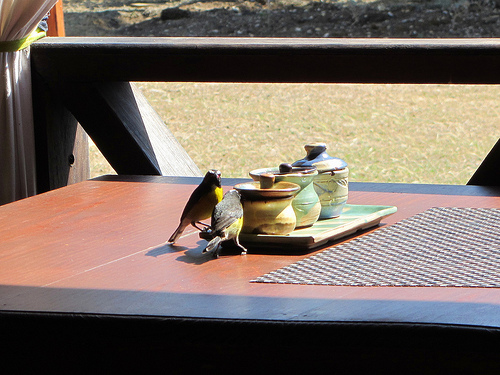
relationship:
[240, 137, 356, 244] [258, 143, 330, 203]
jars have lids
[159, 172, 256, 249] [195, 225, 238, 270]
birds have tail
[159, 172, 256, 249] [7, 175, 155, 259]
birds on table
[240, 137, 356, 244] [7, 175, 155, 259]
jars on table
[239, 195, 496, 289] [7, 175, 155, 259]
mat on top of table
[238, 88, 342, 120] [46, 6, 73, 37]
grass outside window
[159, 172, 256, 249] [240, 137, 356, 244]
birds near jars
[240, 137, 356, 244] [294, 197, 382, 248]
jars on platter